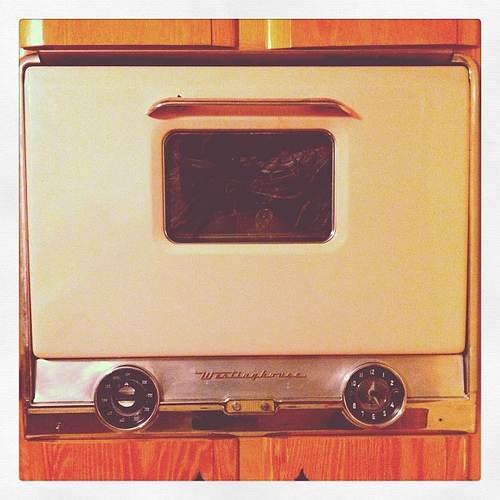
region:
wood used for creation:
[73, 450, 162, 470]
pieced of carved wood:
[203, 433, 293, 481]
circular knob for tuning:
[93, 367, 159, 430]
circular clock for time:
[339, 359, 407, 429]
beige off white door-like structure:
[36, 100, 128, 255]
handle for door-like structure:
[141, 93, 357, 121]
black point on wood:
[291, 466, 311, 483]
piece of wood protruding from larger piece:
[236, 435, 274, 481]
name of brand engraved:
[193, 366, 307, 383]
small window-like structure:
[164, 128, 330, 233]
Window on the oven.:
[136, 72, 400, 278]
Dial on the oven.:
[318, 303, 425, 460]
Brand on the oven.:
[193, 349, 365, 406]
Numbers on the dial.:
[319, 355, 460, 427]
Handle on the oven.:
[136, 72, 431, 133]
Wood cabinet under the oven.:
[91, 409, 339, 489]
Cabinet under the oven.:
[52, 419, 284, 482]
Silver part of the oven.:
[152, 320, 369, 407]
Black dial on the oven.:
[311, 329, 436, 441]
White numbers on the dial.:
[341, 358, 433, 448]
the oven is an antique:
[19, 50, 478, 430]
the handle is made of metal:
[141, 93, 365, 125]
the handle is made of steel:
[148, 93, 359, 120]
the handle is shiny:
[147, 93, 357, 118]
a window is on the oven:
[157, 126, 342, 243]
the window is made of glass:
[159, 129, 338, 246]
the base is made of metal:
[29, 350, 476, 407]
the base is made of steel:
[27, 353, 478, 415]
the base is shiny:
[30, 354, 469, 409]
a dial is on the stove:
[91, 365, 156, 430]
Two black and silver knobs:
[94, 342, 414, 457]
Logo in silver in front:
[190, 363, 312, 394]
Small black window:
[149, 125, 349, 261]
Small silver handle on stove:
[137, 91, 378, 133]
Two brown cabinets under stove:
[19, 436, 479, 487]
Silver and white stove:
[0, 47, 476, 434]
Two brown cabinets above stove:
[0, 13, 479, 57]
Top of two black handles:
[177, 463, 316, 489]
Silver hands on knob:
[362, 382, 394, 414]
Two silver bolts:
[222, 397, 289, 412]